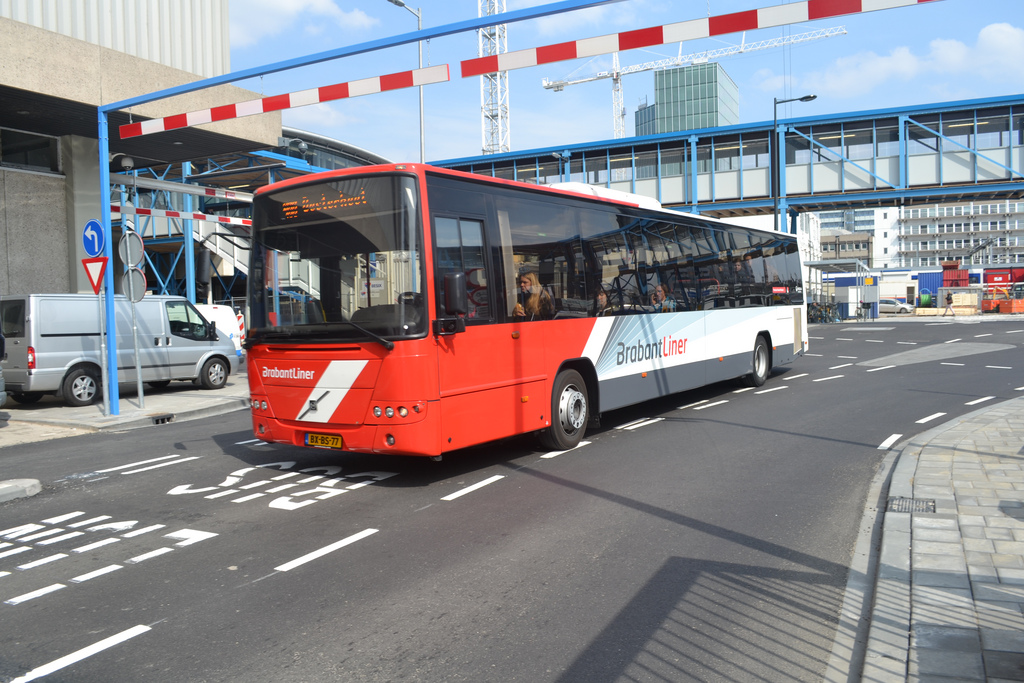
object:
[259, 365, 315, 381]
lettering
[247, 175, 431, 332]
windshield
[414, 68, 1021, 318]
building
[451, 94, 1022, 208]
overpass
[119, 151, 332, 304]
scaffolding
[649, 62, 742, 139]
building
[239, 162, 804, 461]
bus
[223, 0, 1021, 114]
sky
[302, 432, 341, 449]
plate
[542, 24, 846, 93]
crane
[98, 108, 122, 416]
pole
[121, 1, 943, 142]
stripedboards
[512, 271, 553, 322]
woman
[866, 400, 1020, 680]
sidewalk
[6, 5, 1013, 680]
outdoorsscene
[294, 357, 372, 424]
design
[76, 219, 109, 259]
sign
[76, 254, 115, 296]
sign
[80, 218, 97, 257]
arrow